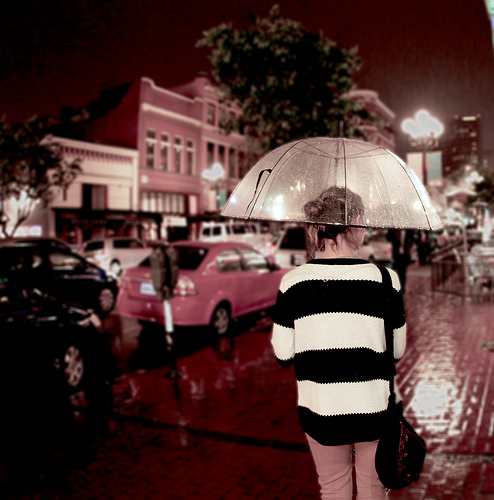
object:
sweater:
[264, 255, 412, 457]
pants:
[299, 426, 400, 500]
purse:
[372, 400, 431, 494]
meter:
[144, 236, 180, 377]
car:
[112, 235, 299, 339]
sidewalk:
[2, 258, 492, 499]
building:
[84, 70, 271, 228]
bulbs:
[198, 160, 231, 185]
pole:
[212, 184, 221, 214]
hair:
[300, 184, 366, 254]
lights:
[395, 104, 448, 144]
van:
[0, 229, 123, 318]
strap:
[379, 262, 399, 410]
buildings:
[323, 83, 401, 204]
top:
[197, 158, 226, 185]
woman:
[264, 176, 417, 500]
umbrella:
[216, 122, 450, 240]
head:
[301, 182, 369, 260]